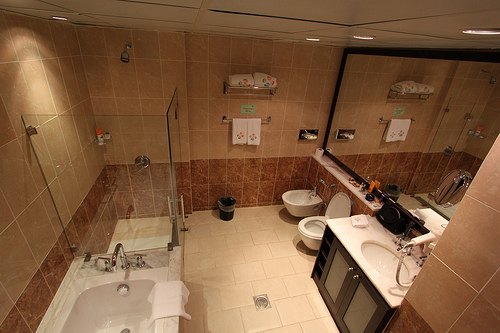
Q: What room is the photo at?
A: It is at the bathroom.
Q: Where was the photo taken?
A: It was taken at the bathroom.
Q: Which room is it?
A: It is a bathroom.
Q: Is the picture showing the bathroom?
A: Yes, it is showing the bathroom.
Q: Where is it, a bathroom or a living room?
A: It is a bathroom.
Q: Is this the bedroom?
A: No, it is the bathroom.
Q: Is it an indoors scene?
A: Yes, it is indoors.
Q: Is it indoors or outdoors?
A: It is indoors.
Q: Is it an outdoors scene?
A: No, it is indoors.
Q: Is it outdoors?
A: No, it is indoors.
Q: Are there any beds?
A: No, there are no beds.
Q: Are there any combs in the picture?
A: No, there are no combs.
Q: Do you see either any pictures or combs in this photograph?
A: No, there are no combs or pictures.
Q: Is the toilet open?
A: Yes, the toilet is open.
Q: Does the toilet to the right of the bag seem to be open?
A: Yes, the toilet is open.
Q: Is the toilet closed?
A: No, the toilet is open.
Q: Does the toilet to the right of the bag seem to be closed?
A: No, the toilet is open.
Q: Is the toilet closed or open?
A: The toilet is open.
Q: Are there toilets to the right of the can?
A: Yes, there is a toilet to the right of the can.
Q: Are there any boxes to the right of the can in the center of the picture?
A: No, there is a toilet to the right of the can.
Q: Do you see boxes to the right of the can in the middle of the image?
A: No, there is a toilet to the right of the can.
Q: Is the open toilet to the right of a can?
A: Yes, the toilet is to the right of a can.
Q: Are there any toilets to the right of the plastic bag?
A: Yes, there is a toilet to the right of the bag.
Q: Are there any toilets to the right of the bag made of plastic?
A: Yes, there is a toilet to the right of the bag.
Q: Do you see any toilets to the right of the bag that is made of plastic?
A: Yes, there is a toilet to the right of the bag.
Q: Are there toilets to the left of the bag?
A: No, the toilet is to the right of the bag.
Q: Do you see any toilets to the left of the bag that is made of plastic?
A: No, the toilet is to the right of the bag.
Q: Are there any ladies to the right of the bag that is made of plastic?
A: No, there is a toilet to the right of the bag.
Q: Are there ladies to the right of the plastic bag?
A: No, there is a toilet to the right of the bag.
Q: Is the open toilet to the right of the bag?
A: Yes, the toilet is to the right of the bag.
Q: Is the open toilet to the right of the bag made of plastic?
A: Yes, the toilet is to the right of the bag.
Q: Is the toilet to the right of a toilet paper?
A: No, the toilet is to the right of the bag.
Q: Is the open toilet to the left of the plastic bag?
A: No, the toilet is to the right of the bag.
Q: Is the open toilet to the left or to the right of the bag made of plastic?
A: The toilet is to the right of the bag.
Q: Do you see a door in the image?
A: Yes, there are doors.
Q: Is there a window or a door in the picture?
A: Yes, there are doors.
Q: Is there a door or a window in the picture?
A: Yes, there are doors.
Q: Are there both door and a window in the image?
A: No, there are doors but no windows.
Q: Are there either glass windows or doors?
A: Yes, there are glass doors.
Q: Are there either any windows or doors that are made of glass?
A: Yes, the doors are made of glass.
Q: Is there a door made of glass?
A: Yes, there are doors that are made of glass.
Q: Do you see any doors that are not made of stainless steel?
A: Yes, there are doors that are made of glass.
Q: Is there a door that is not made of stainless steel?
A: Yes, there are doors that are made of glass.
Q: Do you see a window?
A: No, there are no windows.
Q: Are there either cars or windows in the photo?
A: No, there are no windows or cars.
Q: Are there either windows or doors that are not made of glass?
A: No, there are doors but they are made of glass.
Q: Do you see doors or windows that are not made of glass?
A: No, there are doors but they are made of glass.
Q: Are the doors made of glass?
A: Yes, the doors are made of glass.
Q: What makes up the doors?
A: The doors are made of glass.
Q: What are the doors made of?
A: The doors are made of glass.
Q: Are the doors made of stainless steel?
A: No, the doors are made of glass.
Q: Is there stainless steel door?
A: No, there are doors but they are made of glass.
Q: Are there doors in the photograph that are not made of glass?
A: No, there are doors but they are made of glass.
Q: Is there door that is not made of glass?
A: No, there are doors but they are made of glass.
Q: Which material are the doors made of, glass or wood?
A: The doors are made of glass.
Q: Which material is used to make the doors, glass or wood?
A: The doors are made of glass.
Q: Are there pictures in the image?
A: No, there are no pictures.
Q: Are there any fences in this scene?
A: No, there are no fences.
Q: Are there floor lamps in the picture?
A: No, there are no floor lamps.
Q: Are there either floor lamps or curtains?
A: No, there are no floor lamps or curtains.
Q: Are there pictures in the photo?
A: No, there are no pictures.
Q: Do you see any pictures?
A: No, there are no pictures.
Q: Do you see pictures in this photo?
A: No, there are no pictures.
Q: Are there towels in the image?
A: Yes, there is a towel.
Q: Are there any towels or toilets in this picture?
A: Yes, there is a towel.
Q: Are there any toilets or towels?
A: Yes, there is a towel.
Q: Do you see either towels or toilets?
A: Yes, there is a towel.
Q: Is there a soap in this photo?
A: No, there are no soaps.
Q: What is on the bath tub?
A: The towel is on the bath tub.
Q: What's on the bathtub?
A: The towel is on the bath tub.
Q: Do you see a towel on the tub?
A: Yes, there is a towel on the tub.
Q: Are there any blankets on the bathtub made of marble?
A: No, there is a towel on the bathtub.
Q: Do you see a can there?
A: Yes, there is a can.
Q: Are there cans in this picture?
A: Yes, there is a can.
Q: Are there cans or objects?
A: Yes, there is a can.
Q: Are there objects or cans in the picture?
A: Yes, there is a can.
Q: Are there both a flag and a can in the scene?
A: No, there is a can but no flags.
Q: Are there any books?
A: No, there are no books.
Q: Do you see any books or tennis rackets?
A: No, there are no books or tennis rackets.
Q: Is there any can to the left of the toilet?
A: Yes, there is a can to the left of the toilet.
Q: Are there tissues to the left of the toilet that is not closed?
A: No, there is a can to the left of the toilet.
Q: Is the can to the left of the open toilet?
A: Yes, the can is to the left of the toilet.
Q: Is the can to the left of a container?
A: No, the can is to the left of the toilet.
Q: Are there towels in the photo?
A: Yes, there is a towel.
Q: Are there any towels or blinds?
A: Yes, there is a towel.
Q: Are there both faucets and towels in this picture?
A: Yes, there are both a towel and a faucet.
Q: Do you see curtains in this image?
A: No, there are no curtains.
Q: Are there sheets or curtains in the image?
A: No, there are no curtains or sheets.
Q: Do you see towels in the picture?
A: Yes, there is a towel.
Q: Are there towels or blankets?
A: Yes, there is a towel.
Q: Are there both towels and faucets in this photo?
A: Yes, there are both a towel and a faucet.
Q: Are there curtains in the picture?
A: No, there are no curtains.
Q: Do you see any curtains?
A: No, there are no curtains.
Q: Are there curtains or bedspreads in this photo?
A: No, there are no curtains or bedspreads.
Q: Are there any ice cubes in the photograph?
A: No, there are no ice cubes.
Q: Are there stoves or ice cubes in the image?
A: No, there are no ice cubes or stoves.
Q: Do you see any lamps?
A: No, there are no lamps.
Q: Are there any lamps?
A: No, there are no lamps.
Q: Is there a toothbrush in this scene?
A: No, there are no toothbrushes.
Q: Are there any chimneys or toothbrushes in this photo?
A: No, there are no toothbrushes or chimneys.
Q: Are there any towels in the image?
A: Yes, there is a towel.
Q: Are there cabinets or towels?
A: Yes, there is a towel.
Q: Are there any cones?
A: No, there are no cones.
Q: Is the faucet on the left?
A: Yes, the faucet is on the left of the image.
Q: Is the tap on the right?
A: No, the tap is on the left of the image.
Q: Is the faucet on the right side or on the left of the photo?
A: The faucet is on the left of the image.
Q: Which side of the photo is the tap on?
A: The tap is on the left of the image.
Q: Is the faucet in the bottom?
A: Yes, the faucet is in the bottom of the image.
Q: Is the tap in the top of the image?
A: No, the tap is in the bottom of the image.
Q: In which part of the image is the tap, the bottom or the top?
A: The tap is in the bottom of the image.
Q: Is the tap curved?
A: Yes, the tap is curved.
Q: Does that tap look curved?
A: Yes, the tap is curved.